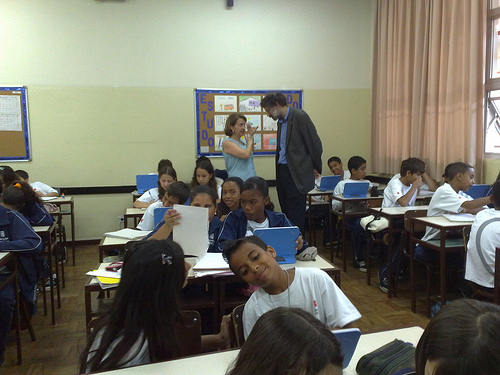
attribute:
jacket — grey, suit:
[271, 110, 321, 195]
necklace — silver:
[280, 274, 295, 301]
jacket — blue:
[221, 210, 240, 235]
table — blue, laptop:
[329, 190, 387, 262]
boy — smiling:
[226, 238, 356, 335]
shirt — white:
[240, 265, 362, 341]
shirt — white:
[135, 186, 164, 209]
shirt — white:
[380, 175, 418, 207]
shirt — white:
[422, 180, 474, 244]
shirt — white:
[330, 176, 371, 211]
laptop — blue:
[315, 173, 342, 190]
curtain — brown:
[373, 3, 473, 169]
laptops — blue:
[152, 148, 493, 352]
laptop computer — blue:
[250, 224, 299, 264]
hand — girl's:
[240, 127, 264, 160]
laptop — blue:
[248, 225, 302, 265]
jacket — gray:
[268, 104, 329, 196]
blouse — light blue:
[220, 132, 256, 187]